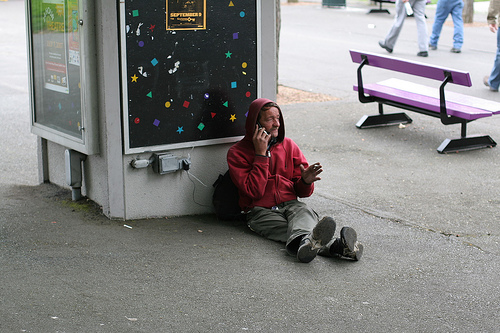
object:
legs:
[247, 203, 339, 253]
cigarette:
[309, 160, 324, 169]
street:
[301, 105, 498, 262]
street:
[59, 217, 289, 324]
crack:
[343, 192, 483, 255]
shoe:
[339, 225, 365, 260]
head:
[249, 95, 280, 139]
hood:
[245, 96, 285, 145]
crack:
[426, 227, 463, 242]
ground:
[6, 10, 495, 327]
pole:
[258, 1, 283, 103]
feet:
[303, 223, 334, 260]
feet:
[337, 217, 420, 264]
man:
[232, 79, 472, 308]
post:
[110, 1, 266, 158]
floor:
[5, 1, 495, 327]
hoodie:
[224, 97, 316, 211]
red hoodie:
[222, 94, 319, 205]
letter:
[176, 11, 180, 18]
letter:
[198, 10, 203, 18]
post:
[21, 26, 87, 142]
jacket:
[229, 137, 314, 207]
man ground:
[233, 96, 385, 287]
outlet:
[181, 155, 191, 172]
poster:
[122, 1, 262, 154]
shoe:
[297, 215, 335, 262]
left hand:
[294, 153, 326, 188]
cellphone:
[258, 125, 267, 140]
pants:
[239, 197, 339, 252]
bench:
[344, 47, 486, 142]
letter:
[170, 9, 172, 18]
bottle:
[402, 0, 421, 23]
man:
[373, 0, 435, 59]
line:
[318, 191, 487, 251]